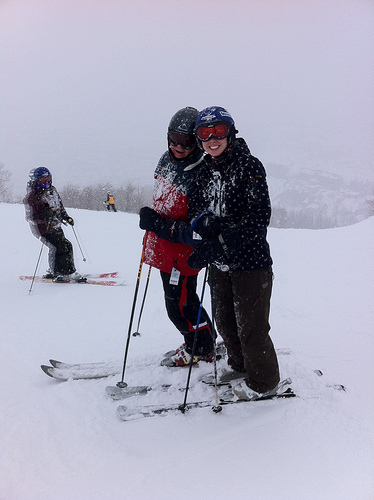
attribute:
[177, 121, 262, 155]
goggles — red, orange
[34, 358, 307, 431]
skis — snow-covered, black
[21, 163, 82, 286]
person — skiing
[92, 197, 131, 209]
coat — yellow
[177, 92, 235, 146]
helmet — blue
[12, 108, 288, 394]
people — skiing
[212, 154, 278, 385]
clothing — dark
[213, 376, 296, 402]
boots — grey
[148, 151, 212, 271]
coat — red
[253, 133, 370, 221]
mountain — snow-covered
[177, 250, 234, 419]
poles — black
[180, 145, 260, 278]
jacket — polka-dotted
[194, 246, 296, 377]
pants — brown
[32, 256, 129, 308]
skis — red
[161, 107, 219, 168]
helmet — black